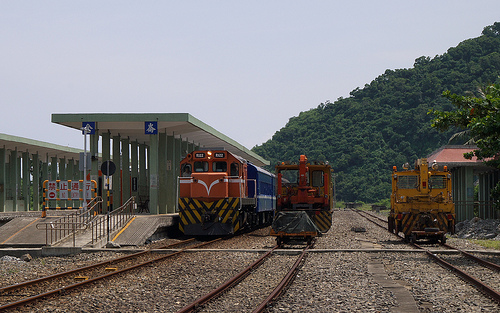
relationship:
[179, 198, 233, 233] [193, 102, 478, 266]
bumper of trains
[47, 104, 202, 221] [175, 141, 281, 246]
platform near train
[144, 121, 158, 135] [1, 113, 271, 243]
pictures on platform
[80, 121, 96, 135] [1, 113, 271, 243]
sign on platform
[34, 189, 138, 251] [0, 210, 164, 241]
handrails on ramp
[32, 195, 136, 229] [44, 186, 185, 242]
railling near platform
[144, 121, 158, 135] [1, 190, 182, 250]
pictures on platform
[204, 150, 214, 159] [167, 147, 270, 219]
light on train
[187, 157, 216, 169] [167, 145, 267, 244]
window on train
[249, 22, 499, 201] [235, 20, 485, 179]
trees on hillside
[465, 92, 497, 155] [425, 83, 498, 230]
leaves on tree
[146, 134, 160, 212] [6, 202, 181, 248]
beam on platform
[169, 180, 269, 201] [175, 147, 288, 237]
white lines on train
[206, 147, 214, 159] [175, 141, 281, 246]
light on train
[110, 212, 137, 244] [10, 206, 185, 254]
yellow line on pavement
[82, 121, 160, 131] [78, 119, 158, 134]
pictures on signs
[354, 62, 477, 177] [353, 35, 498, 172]
hillside covered in trees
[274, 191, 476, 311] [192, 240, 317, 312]
pebbles near track